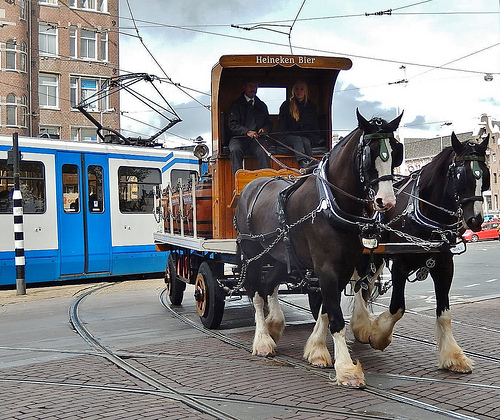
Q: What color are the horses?
A: Brown.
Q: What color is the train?
A: Blue and white.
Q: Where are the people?
A: On the wagon.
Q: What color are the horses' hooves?
A: White.